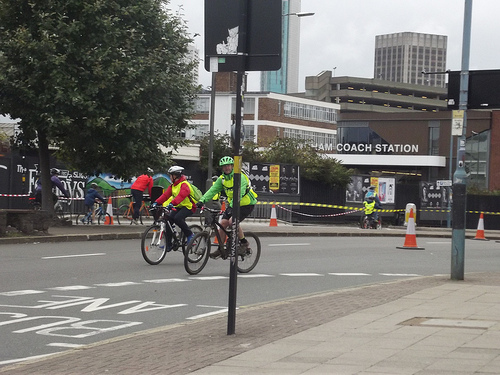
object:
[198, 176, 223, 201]
arm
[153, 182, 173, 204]
arm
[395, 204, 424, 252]
cone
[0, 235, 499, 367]
street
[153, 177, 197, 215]
jacket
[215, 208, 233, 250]
leg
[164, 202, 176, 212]
hand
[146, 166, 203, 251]
boy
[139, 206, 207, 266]
bike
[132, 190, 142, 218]
leg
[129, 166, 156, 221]
person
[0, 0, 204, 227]
tree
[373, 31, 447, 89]
building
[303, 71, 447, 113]
garage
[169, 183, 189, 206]
arm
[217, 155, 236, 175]
head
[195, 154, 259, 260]
person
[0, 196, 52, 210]
bench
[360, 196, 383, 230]
father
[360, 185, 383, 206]
son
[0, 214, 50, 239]
grass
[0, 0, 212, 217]
park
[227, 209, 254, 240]
leg